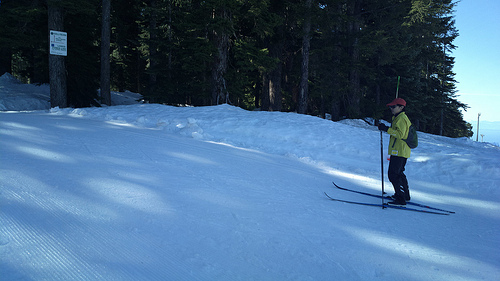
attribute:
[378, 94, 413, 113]
hat — red 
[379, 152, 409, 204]
pants — black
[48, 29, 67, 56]
sign — posted 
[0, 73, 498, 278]
snow — white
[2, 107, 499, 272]
hill — edge 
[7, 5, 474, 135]
trees — shadow  , edge 